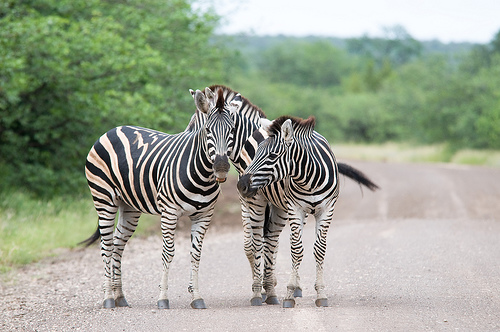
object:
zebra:
[76, 89, 236, 310]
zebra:
[184, 84, 288, 304]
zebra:
[236, 115, 380, 307]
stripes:
[105, 127, 144, 208]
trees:
[1, 0, 255, 203]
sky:
[186, 3, 498, 47]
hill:
[1, 0, 497, 211]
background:
[0, 1, 499, 169]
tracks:
[375, 160, 468, 220]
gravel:
[5, 278, 93, 330]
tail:
[337, 161, 379, 192]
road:
[2, 135, 499, 332]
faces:
[207, 133, 234, 158]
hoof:
[190, 297, 207, 309]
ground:
[1, 160, 499, 331]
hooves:
[101, 296, 117, 309]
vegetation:
[183, 44, 495, 143]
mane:
[268, 115, 317, 136]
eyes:
[230, 128, 235, 134]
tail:
[75, 219, 100, 251]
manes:
[206, 83, 265, 114]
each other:
[182, 83, 269, 183]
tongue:
[216, 178, 226, 182]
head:
[193, 88, 242, 183]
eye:
[206, 127, 212, 133]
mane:
[214, 87, 226, 112]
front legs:
[156, 209, 178, 311]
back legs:
[92, 203, 117, 311]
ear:
[194, 88, 207, 115]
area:
[0, 131, 499, 332]